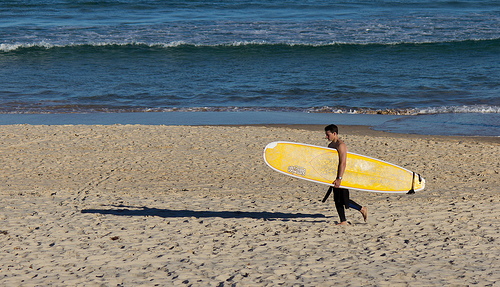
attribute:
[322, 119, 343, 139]
hair — dark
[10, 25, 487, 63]
wave — small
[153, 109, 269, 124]
beach — wet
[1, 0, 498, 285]
beach — sandy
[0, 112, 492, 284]
beach — sandy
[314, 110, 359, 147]
hair — dark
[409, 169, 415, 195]
leash — black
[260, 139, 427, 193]
surfboard — yellow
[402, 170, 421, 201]
strap — black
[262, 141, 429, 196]
surfboard — big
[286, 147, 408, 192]
spots — white